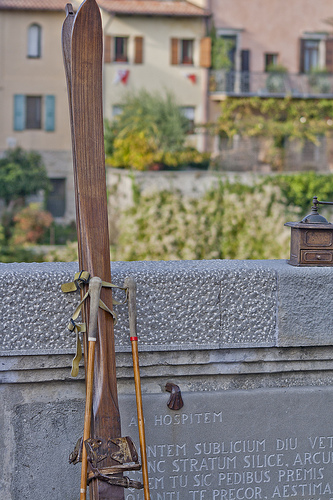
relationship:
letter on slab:
[24, 385, 331, 494] [3, 261, 331, 498]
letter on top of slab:
[24, 385, 331, 494] [3, 261, 331, 498]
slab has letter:
[3, 261, 331, 498] [24, 385, 331, 494]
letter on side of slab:
[24, 385, 331, 494] [3, 261, 331, 498]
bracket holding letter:
[159, 378, 184, 410] [24, 385, 331, 494]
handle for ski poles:
[125, 280, 150, 499] [71, 1, 123, 500]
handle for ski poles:
[75, 276, 101, 499] [71, 1, 123, 500]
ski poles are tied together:
[71, 1, 123, 500] [57, 0, 124, 494]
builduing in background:
[205, 5, 329, 264] [1, 1, 329, 267]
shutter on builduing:
[42, 96, 57, 133] [2, 5, 211, 260]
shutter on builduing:
[12, 93, 31, 132] [2, 5, 211, 260]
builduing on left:
[2, 5, 211, 260] [0, 6, 212, 270]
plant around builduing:
[207, 96, 330, 150] [205, 5, 329, 264]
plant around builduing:
[280, 177, 331, 217] [205, 5, 329, 264]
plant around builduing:
[0, 148, 55, 198] [2, 5, 211, 260]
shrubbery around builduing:
[114, 181, 285, 260] [205, 5, 329, 264]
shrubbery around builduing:
[104, 94, 203, 168] [205, 5, 329, 264]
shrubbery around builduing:
[1, 207, 71, 268] [2, 5, 211, 260]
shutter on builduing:
[199, 39, 214, 73] [2, 5, 211, 260]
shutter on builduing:
[166, 38, 184, 67] [2, 5, 211, 260]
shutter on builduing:
[132, 35, 146, 63] [2, 5, 211, 260]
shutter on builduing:
[98, 34, 117, 64] [2, 5, 211, 260]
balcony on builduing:
[214, 71, 330, 104] [205, 5, 329, 264]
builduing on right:
[205, 5, 329, 264] [205, 0, 332, 291]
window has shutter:
[112, 34, 133, 70] [132, 35, 146, 63]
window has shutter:
[112, 34, 133, 70] [98, 34, 117, 64]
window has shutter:
[180, 39, 195, 68] [199, 39, 214, 73]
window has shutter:
[180, 39, 195, 68] [166, 38, 184, 67]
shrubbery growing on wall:
[114, 181, 285, 260] [111, 166, 289, 260]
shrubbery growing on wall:
[104, 94, 203, 168] [108, 17, 209, 169]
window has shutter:
[21, 94, 50, 134] [42, 96, 57, 133]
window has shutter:
[21, 94, 50, 134] [12, 93, 31, 132]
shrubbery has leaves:
[114, 181, 285, 260] [118, 178, 286, 263]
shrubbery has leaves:
[104, 94, 203, 168] [110, 108, 189, 167]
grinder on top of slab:
[293, 205, 332, 266] [3, 261, 331, 498]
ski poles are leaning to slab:
[71, 1, 123, 500] [3, 261, 331, 498]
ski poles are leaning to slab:
[61, 16, 72, 154] [3, 261, 331, 498]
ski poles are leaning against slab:
[71, 1, 123, 500] [3, 261, 331, 498]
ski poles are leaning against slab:
[61, 16, 72, 154] [3, 261, 331, 498]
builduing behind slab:
[205, 5, 329, 264] [3, 261, 331, 498]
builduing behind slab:
[2, 5, 211, 260] [3, 261, 331, 498]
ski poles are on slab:
[71, 1, 123, 500] [3, 261, 331, 498]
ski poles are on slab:
[61, 16, 72, 154] [3, 261, 331, 498]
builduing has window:
[2, 5, 211, 260] [112, 34, 133, 70]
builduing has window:
[2, 5, 211, 260] [180, 39, 195, 68]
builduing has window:
[2, 5, 211, 260] [21, 94, 50, 134]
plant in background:
[207, 96, 330, 150] [1, 1, 329, 267]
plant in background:
[280, 177, 331, 217] [1, 1, 329, 267]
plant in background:
[0, 148, 55, 198] [1, 1, 329, 267]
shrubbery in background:
[114, 181, 285, 260] [1, 1, 329, 267]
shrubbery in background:
[104, 94, 203, 168] [1, 1, 329, 267]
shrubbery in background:
[1, 207, 71, 268] [1, 1, 329, 267]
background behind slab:
[1, 1, 329, 267] [3, 261, 331, 498]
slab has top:
[3, 261, 331, 498] [2, 261, 330, 301]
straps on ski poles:
[78, 432, 134, 490] [71, 1, 123, 500]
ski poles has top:
[71, 1, 123, 500] [72, 2, 102, 49]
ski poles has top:
[61, 16, 72, 154] [63, 15, 74, 54]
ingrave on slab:
[133, 417, 329, 498] [3, 261, 331, 498]